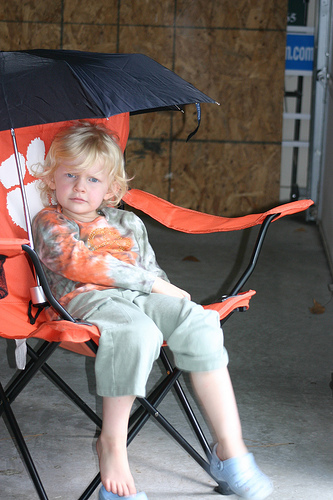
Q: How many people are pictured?
A: One.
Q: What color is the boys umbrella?
A: Black.